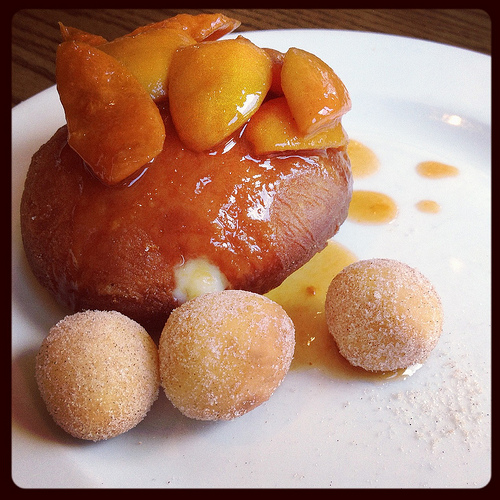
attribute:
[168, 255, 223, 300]
stuff — white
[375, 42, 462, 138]
plate — white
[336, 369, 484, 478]
sprinkles — white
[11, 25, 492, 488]
plate — white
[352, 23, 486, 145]
plate — round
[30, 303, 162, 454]
food — ball shapped, light yellow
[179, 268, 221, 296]
stuff — white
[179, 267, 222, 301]
stuff — white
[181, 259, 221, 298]
stuff — white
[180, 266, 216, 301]
stuff — white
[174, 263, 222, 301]
stuff — white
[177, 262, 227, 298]
stuff — white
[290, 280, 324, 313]
syrup — light brown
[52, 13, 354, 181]
peaches — soaked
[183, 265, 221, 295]
cream — white